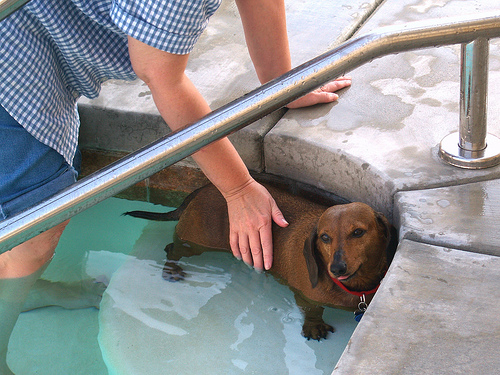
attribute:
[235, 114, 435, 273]
pavement — curved, wet, concrete